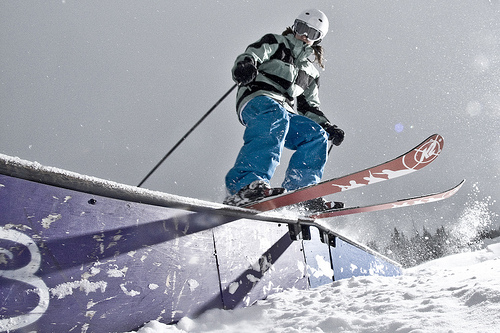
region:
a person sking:
[227, 6, 352, 230]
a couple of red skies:
[225, 131, 468, 223]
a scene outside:
[2, 5, 499, 330]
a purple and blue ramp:
[0, 166, 409, 331]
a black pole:
[134, 57, 262, 192]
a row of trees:
[355, 207, 498, 272]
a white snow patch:
[131, 240, 496, 330]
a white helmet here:
[290, 5, 326, 35]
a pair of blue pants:
[227, 85, 330, 235]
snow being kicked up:
[441, 185, 498, 253]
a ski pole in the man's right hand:
[133, 61, 258, 185]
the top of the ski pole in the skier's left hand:
[326, 125, 346, 160]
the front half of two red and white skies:
[243, 132, 465, 218]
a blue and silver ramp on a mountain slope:
[1, 152, 403, 330]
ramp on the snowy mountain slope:
[2, 153, 404, 331]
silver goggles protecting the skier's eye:
[292, 17, 324, 42]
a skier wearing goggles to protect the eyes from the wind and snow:
[292, 17, 321, 42]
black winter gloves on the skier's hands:
[232, 55, 345, 147]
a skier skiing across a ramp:
[2, 2, 497, 330]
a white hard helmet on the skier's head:
[297, 6, 327, 34]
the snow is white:
[372, 294, 385, 316]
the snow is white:
[354, 300, 376, 329]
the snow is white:
[354, 298, 365, 330]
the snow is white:
[347, 303, 362, 330]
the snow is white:
[347, 285, 361, 325]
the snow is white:
[350, 271, 367, 319]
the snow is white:
[356, 270, 373, 307]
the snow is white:
[357, 298, 371, 323]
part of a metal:
[226, 204, 261, 218]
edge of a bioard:
[362, 152, 387, 175]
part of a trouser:
[251, 127, 276, 162]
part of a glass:
[205, 268, 230, 308]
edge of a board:
[423, 130, 438, 147]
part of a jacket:
[276, 77, 303, 110]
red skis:
[220, 122, 460, 247]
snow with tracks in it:
[287, 281, 423, 326]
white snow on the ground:
[422, 258, 498, 314]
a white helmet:
[282, 10, 344, 45]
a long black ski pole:
[110, 52, 243, 192]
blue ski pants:
[218, 89, 356, 211]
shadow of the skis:
[1, 192, 316, 328]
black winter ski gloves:
[226, 48, 281, 98]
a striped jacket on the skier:
[230, 16, 358, 144]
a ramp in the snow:
[5, 130, 426, 323]